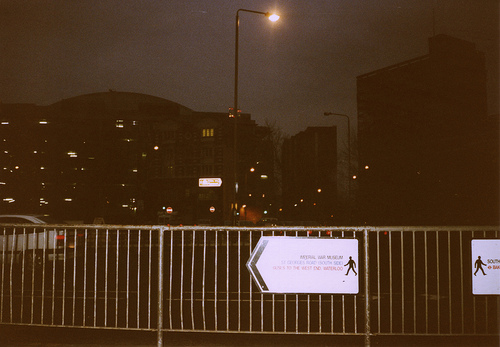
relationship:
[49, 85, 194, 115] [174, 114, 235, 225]
mountain near building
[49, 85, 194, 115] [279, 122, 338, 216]
mountain near building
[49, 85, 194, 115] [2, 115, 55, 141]
mountain near building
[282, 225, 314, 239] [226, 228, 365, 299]
edge of a board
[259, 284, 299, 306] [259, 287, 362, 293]
edge of a board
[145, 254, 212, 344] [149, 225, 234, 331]
part of a metal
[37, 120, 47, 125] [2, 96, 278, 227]
light shining in building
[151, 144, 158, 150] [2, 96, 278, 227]
light shining in building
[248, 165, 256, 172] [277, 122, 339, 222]
light shining in building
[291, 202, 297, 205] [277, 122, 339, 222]
light shining in building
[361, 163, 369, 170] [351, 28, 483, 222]
light shining in building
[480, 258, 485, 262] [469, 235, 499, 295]
south painted on sign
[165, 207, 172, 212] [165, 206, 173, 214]
stop painted on signs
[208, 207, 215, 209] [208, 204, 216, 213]
stop painted on street sign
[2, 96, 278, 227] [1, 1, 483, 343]
building seen in picture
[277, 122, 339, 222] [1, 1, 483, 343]
building seen in picture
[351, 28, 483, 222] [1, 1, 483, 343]
building seen in picture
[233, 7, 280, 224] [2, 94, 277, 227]
street light lighting place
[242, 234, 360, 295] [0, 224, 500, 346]
advertisement board hanging on fence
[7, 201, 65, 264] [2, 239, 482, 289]
car parked parked in parking area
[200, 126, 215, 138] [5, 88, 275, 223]
window adorning building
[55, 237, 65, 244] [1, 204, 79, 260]
light of car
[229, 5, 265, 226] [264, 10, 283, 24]
post of street light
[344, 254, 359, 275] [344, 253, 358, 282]
image of a person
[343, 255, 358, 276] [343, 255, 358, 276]
image of a image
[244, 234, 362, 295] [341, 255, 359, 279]
advertisement board with an image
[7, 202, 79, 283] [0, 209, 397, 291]
car on street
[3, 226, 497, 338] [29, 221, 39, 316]
fence made of iron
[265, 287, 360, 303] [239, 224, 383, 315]
edge of a board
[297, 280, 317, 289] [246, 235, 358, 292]
part of a board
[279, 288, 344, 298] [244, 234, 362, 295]
edge of a advertisement board